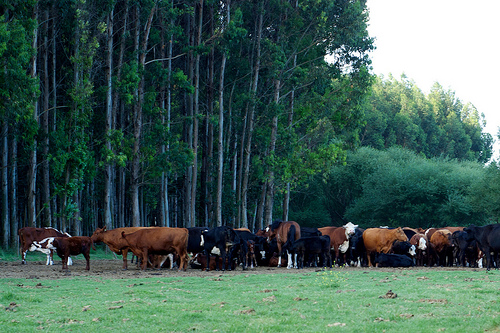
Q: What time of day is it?
A: Daytime.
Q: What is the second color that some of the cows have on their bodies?
A: White.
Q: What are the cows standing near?
A: Trees.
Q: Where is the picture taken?
A: On a field.